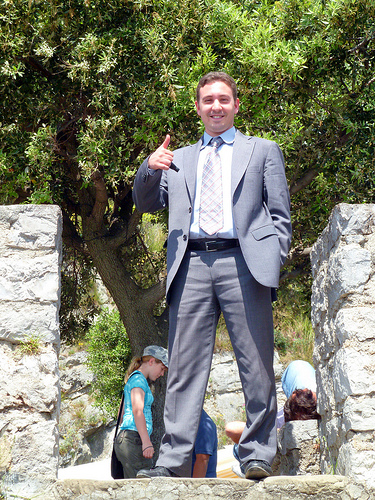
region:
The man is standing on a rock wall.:
[0, 194, 374, 498]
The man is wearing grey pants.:
[154, 248, 279, 479]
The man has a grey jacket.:
[133, 130, 294, 307]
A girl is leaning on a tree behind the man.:
[110, 343, 170, 476]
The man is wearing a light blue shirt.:
[183, 124, 240, 242]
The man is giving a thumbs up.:
[149, 131, 176, 171]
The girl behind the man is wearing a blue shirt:
[119, 367, 153, 441]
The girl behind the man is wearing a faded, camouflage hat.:
[142, 343, 173, 371]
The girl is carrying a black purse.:
[110, 370, 142, 480]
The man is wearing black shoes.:
[134, 460, 273, 483]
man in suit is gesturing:
[132, 70, 293, 478]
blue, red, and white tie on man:
[198, 136, 224, 236]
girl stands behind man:
[111, 344, 168, 479]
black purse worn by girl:
[110, 371, 142, 478]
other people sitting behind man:
[190, 359, 322, 477]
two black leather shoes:
[136, 459, 273, 479]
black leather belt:
[186, 238, 239, 251]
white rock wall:
[0, 201, 374, 498]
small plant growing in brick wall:
[21, 336, 41, 355]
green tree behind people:
[0, 0, 374, 467]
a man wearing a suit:
[129, 71, 291, 474]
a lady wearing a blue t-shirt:
[113, 343, 168, 429]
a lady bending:
[283, 356, 316, 416]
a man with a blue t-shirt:
[194, 413, 220, 477]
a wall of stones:
[312, 273, 372, 491]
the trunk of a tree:
[105, 273, 174, 344]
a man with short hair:
[192, 69, 243, 132]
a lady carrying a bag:
[107, 344, 168, 477]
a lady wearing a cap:
[141, 346, 169, 378]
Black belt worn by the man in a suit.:
[184, 237, 241, 254]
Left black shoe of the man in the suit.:
[130, 455, 183, 479]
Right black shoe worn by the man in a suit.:
[237, 456, 277, 480]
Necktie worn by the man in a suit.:
[195, 139, 227, 236]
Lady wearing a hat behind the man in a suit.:
[112, 345, 158, 469]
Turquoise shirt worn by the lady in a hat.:
[128, 366, 151, 438]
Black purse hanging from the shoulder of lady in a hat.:
[111, 383, 122, 479]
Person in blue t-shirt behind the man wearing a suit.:
[200, 411, 222, 483]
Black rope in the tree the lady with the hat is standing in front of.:
[72, 200, 162, 276]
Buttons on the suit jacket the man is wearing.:
[182, 191, 193, 246]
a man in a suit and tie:
[139, 70, 302, 373]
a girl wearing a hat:
[120, 342, 177, 393]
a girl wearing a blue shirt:
[115, 345, 169, 455]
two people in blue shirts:
[105, 347, 237, 467]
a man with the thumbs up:
[156, 64, 248, 180]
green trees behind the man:
[22, 19, 308, 203]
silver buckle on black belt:
[180, 231, 243, 254]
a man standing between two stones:
[24, 73, 348, 486]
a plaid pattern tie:
[200, 142, 225, 235]